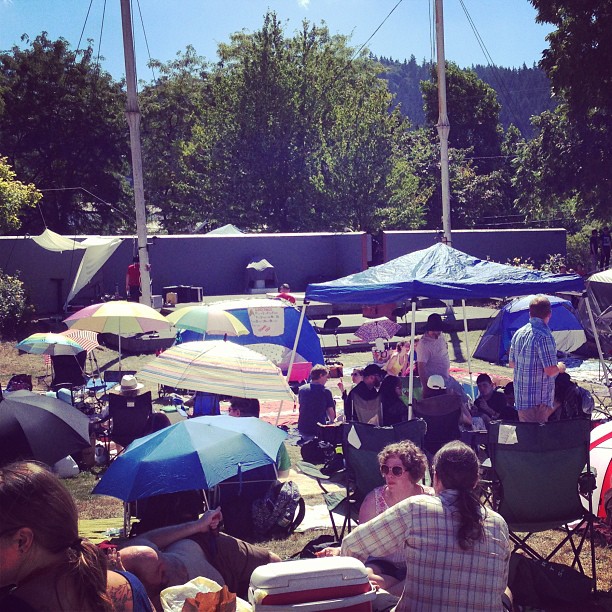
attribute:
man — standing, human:
[507, 298, 567, 422]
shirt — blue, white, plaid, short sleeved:
[508, 320, 559, 409]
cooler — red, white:
[245, 560, 391, 607]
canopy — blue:
[335, 239, 579, 324]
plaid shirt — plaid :
[337, 484, 510, 597]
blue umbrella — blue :
[90, 390, 302, 505]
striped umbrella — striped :
[143, 323, 309, 426]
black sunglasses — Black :
[377, 464, 410, 481]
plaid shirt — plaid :
[510, 318, 566, 401]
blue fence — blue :
[7, 231, 587, 326]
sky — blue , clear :
[370, 3, 517, 63]